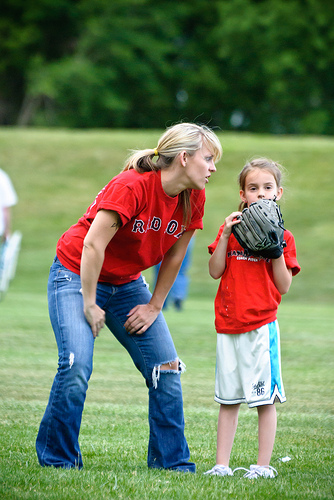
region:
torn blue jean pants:
[28, 246, 204, 486]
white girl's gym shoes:
[201, 457, 286, 490]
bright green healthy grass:
[92, 416, 143, 485]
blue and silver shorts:
[209, 324, 293, 414]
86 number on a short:
[249, 379, 273, 397]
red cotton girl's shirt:
[204, 210, 307, 335]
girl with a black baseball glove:
[229, 156, 297, 266]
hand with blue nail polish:
[119, 300, 166, 342]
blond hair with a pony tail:
[121, 103, 225, 191]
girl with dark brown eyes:
[244, 175, 281, 194]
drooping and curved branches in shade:
[0, 1, 327, 128]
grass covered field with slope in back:
[1, 125, 328, 489]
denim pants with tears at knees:
[30, 250, 194, 474]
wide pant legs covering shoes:
[30, 387, 197, 482]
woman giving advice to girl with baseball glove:
[119, 118, 279, 215]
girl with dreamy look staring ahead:
[235, 153, 281, 209]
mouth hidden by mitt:
[242, 183, 276, 212]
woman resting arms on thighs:
[77, 192, 191, 333]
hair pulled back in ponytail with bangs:
[116, 118, 220, 171]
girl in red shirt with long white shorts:
[205, 156, 289, 413]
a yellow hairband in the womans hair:
[149, 138, 161, 164]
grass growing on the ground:
[94, 463, 122, 487]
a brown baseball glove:
[232, 204, 282, 253]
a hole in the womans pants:
[152, 351, 186, 379]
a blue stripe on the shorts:
[265, 329, 282, 368]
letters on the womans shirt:
[139, 210, 174, 236]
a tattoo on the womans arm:
[104, 211, 127, 235]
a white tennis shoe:
[241, 456, 284, 481]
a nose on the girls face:
[253, 187, 269, 198]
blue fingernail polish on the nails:
[122, 307, 138, 319]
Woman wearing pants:
[35, 243, 200, 474]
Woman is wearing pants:
[32, 248, 201, 475]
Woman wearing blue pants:
[33, 247, 200, 472]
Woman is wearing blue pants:
[33, 245, 201, 476]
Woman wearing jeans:
[34, 247, 199, 475]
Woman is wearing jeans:
[32, 247, 200, 475]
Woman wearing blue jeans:
[32, 250, 199, 475]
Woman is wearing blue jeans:
[32, 251, 202, 476]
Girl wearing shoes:
[194, 460, 282, 487]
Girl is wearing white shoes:
[203, 459, 280, 480]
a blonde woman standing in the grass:
[33, 118, 222, 472]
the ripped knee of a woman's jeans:
[150, 355, 184, 375]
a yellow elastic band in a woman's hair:
[153, 147, 159, 155]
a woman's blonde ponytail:
[124, 148, 154, 171]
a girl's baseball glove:
[232, 200, 285, 256]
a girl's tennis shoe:
[239, 463, 279, 481]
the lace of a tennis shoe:
[233, 465, 249, 474]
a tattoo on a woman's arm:
[110, 217, 120, 235]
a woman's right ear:
[179, 150, 188, 169]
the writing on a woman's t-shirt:
[131, 213, 185, 241]